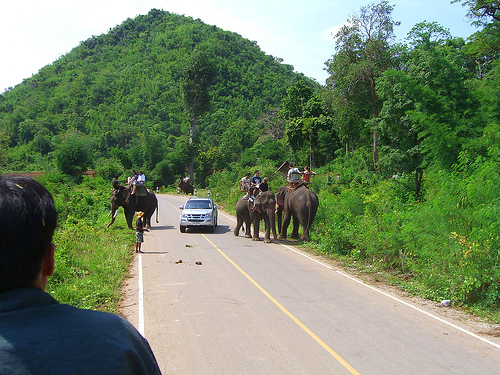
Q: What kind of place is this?
A: It is a road.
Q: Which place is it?
A: It is a road.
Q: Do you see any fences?
A: No, there are no fences.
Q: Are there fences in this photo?
A: No, there are no fences.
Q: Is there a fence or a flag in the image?
A: No, there are no fences or flags.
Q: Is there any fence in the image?
A: No, there are no fences.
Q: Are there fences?
A: No, there are no fences.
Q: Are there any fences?
A: No, there are no fences.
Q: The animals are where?
A: The animals are on the road.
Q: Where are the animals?
A: The animals are on the road.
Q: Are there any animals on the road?
A: Yes, there are animals on the road.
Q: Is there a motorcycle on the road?
A: No, there are animals on the road.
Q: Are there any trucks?
A: Yes, there is a truck.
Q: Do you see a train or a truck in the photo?
A: Yes, there is a truck.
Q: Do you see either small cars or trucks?
A: Yes, there is a small truck.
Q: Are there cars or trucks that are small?
A: Yes, the truck is small.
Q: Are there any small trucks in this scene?
A: Yes, there is a small truck.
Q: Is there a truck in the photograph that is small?
A: Yes, there is a truck that is small.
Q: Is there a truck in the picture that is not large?
A: Yes, there is a small truck.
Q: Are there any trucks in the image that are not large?
A: Yes, there is a small truck.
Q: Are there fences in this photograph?
A: No, there are no fences.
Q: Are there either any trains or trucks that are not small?
A: No, there is a truck but it is small.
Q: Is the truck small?
A: Yes, the truck is small.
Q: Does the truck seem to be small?
A: Yes, the truck is small.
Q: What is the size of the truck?
A: The truck is small.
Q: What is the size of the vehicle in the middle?
A: The truck is small.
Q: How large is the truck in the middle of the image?
A: The truck is small.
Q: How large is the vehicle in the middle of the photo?
A: The truck is small.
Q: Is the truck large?
A: No, the truck is small.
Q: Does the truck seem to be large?
A: No, the truck is small.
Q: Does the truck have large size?
A: No, the truck is small.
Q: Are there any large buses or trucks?
A: No, there is a truck but it is small.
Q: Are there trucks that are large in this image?
A: No, there is a truck but it is small.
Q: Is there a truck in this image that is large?
A: No, there is a truck but it is small.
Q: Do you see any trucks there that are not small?
A: No, there is a truck but it is small.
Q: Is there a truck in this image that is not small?
A: No, there is a truck but it is small.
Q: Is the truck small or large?
A: The truck is small.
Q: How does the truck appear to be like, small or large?
A: The truck is small.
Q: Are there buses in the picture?
A: No, there are no buses.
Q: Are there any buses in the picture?
A: No, there are no buses.